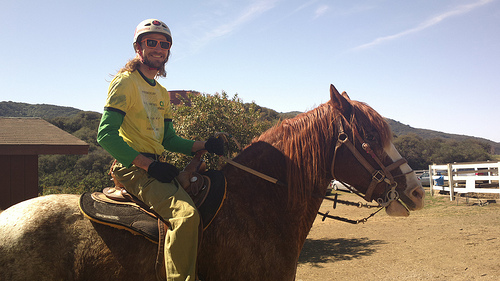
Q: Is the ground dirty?
A: Yes, the ground is dirty.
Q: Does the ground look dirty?
A: Yes, the ground is dirty.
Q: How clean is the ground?
A: The ground is dirty.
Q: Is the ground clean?
A: No, the ground is dirty.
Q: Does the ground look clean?
A: No, the ground is dirty.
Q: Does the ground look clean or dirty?
A: The ground is dirty.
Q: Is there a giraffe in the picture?
A: No, there are no giraffes.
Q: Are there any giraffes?
A: No, there are no giraffes.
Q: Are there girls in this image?
A: No, there are no girls.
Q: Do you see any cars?
A: No, there are no cars.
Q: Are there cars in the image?
A: No, there are no cars.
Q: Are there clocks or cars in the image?
A: No, there are no cars or clocks.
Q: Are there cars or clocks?
A: No, there are no cars or clocks.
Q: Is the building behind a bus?
A: No, the building is behind a man.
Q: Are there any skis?
A: No, there are no skis.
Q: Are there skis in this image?
A: No, there are no skis.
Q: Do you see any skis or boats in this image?
A: No, there are no skis or boats.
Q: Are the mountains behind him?
A: Yes, the mountains are behind the man.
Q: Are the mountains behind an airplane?
A: No, the mountains are behind the man.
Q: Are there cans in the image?
A: No, there are no cans.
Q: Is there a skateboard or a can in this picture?
A: No, there are no cans or skateboards.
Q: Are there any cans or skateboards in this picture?
A: No, there are no cans or skateboards.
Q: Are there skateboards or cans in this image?
A: No, there are no cans or skateboards.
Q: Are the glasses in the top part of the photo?
A: Yes, the glasses are in the top of the image.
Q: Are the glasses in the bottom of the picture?
A: No, the glasses are in the top of the image.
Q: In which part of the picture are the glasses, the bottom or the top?
A: The glasses are in the top of the image.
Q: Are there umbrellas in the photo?
A: No, there are no umbrellas.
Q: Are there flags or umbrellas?
A: No, there are no umbrellas or flags.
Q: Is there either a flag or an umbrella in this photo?
A: No, there are no umbrellas or flags.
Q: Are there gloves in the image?
A: Yes, there are gloves.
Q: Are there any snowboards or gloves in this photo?
A: Yes, there are gloves.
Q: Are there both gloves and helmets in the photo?
A: Yes, there are both gloves and a helmet.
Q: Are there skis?
A: No, there are no skis.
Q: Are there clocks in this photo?
A: No, there are no clocks.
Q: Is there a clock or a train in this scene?
A: No, there are no clocks or trains.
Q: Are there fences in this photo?
A: Yes, there is a fence.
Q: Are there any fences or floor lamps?
A: Yes, there is a fence.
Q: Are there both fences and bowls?
A: No, there is a fence but no bowls.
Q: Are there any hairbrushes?
A: No, there are no hairbrushes.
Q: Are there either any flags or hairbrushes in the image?
A: No, there are no hairbrushes or flags.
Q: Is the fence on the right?
A: Yes, the fence is on the right of the image.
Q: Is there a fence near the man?
A: Yes, there is a fence near the man.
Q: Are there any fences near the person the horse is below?
A: Yes, there is a fence near the man.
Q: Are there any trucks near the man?
A: No, there is a fence near the man.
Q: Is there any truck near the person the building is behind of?
A: No, there is a fence near the man.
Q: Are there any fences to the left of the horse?
A: No, the fence is to the right of the horse.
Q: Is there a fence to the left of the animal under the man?
A: No, the fence is to the right of the horse.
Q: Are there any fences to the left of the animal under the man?
A: No, the fence is to the right of the horse.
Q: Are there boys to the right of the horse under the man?
A: No, there is a fence to the right of the horse.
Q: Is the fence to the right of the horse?
A: Yes, the fence is to the right of the horse.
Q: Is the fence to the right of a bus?
A: No, the fence is to the right of the horse.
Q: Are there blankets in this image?
A: Yes, there is a blanket.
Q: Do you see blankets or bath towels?
A: Yes, there is a blanket.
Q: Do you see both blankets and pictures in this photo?
A: No, there is a blanket but no pictures.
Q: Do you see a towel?
A: No, there are no towels.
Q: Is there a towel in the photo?
A: No, there are no towels.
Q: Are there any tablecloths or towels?
A: No, there are no towels or tablecloths.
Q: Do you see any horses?
A: Yes, there is a horse.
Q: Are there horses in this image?
A: Yes, there is a horse.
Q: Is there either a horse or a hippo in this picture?
A: Yes, there is a horse.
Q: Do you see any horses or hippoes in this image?
A: Yes, there is a horse.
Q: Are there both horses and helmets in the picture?
A: Yes, there are both a horse and a helmet.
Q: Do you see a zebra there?
A: No, there are no zebras.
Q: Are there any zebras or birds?
A: No, there are no zebras or birds.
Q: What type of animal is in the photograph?
A: The animal is a horse.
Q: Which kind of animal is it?
A: The animal is a horse.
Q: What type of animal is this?
A: This is a horse.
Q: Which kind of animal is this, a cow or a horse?
A: This is a horse.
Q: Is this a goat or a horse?
A: This is a horse.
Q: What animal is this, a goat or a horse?
A: This is a horse.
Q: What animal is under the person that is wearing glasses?
A: The horse is under the man.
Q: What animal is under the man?
A: The horse is under the man.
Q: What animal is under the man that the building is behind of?
A: The animal is a horse.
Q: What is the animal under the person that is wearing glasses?
A: The animal is a horse.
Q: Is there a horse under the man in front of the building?
A: Yes, there is a horse under the man.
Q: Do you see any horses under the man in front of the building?
A: Yes, there is a horse under the man.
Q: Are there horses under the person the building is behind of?
A: Yes, there is a horse under the man.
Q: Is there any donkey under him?
A: No, there is a horse under the man.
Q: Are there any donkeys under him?
A: No, there is a horse under the man.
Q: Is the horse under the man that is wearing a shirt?
A: Yes, the horse is under the man.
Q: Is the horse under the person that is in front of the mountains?
A: Yes, the horse is under the man.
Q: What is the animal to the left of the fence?
A: The animal is a horse.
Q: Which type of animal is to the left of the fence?
A: The animal is a horse.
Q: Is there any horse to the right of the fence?
A: No, the horse is to the left of the fence.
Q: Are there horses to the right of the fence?
A: No, the horse is to the left of the fence.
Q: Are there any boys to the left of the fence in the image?
A: No, there is a horse to the left of the fence.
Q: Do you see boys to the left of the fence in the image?
A: No, there is a horse to the left of the fence.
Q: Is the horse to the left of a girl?
A: No, the horse is to the left of a fence.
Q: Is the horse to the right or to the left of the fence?
A: The horse is to the left of the fence.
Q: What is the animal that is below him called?
A: The animal is a horse.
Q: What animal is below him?
A: The animal is a horse.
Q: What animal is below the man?
A: The animal is a horse.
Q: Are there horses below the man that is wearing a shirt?
A: Yes, there is a horse below the man.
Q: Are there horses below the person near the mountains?
A: Yes, there is a horse below the man.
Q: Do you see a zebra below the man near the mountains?
A: No, there is a horse below the man.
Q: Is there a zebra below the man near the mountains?
A: No, there is a horse below the man.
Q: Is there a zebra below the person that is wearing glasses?
A: No, there is a horse below the man.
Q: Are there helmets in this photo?
A: Yes, there is a helmet.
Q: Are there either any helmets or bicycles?
A: Yes, there is a helmet.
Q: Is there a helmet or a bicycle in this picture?
A: Yes, there is a helmet.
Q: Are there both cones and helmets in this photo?
A: No, there is a helmet but no cones.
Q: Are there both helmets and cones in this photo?
A: No, there is a helmet but no cones.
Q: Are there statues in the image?
A: No, there are no statues.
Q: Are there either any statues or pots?
A: No, there are no statues or pots.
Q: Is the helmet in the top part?
A: Yes, the helmet is in the top of the image.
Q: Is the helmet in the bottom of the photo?
A: No, the helmet is in the top of the image.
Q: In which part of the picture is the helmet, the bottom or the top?
A: The helmet is in the top of the image.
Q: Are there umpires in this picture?
A: No, there are no umpires.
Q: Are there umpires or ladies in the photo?
A: No, there are no umpires or ladies.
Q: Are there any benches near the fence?
A: No, there is a man near the fence.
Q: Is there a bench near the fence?
A: No, there is a man near the fence.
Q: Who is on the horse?
A: The man is on the horse.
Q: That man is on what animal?
A: The man is on the horse.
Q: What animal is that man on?
A: The man is on the horse.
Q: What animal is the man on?
A: The man is on the horse.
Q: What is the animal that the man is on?
A: The animal is a horse.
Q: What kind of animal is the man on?
A: The man is on the horse.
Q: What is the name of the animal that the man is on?
A: The animal is a horse.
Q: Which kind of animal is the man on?
A: The man is on the horse.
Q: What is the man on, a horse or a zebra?
A: The man is on a horse.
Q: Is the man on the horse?
A: Yes, the man is on the horse.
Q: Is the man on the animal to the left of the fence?
A: Yes, the man is on the horse.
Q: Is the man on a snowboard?
A: No, the man is on the horse.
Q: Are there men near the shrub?
A: Yes, there is a man near the shrub.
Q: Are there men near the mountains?
A: Yes, there is a man near the mountains.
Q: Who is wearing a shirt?
A: The man is wearing a shirt.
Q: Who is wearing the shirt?
A: The man is wearing a shirt.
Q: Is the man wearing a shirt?
A: Yes, the man is wearing a shirt.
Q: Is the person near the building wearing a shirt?
A: Yes, the man is wearing a shirt.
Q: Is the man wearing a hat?
A: No, the man is wearing a shirt.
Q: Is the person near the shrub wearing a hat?
A: No, the man is wearing a shirt.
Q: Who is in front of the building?
A: The man is in front of the building.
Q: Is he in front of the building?
A: Yes, the man is in front of the building.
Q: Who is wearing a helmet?
A: The man is wearing a helmet.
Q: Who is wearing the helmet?
A: The man is wearing a helmet.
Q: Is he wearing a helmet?
A: Yes, the man is wearing a helmet.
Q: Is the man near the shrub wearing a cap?
A: No, the man is wearing a helmet.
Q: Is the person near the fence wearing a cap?
A: No, the man is wearing a helmet.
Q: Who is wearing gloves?
A: The man is wearing gloves.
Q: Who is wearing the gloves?
A: The man is wearing gloves.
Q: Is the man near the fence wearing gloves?
A: Yes, the man is wearing gloves.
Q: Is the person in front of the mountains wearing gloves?
A: Yes, the man is wearing gloves.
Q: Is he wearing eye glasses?
A: No, the man is wearing gloves.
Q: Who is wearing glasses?
A: The man is wearing glasses.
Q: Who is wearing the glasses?
A: The man is wearing glasses.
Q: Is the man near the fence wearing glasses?
A: Yes, the man is wearing glasses.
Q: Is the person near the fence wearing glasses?
A: Yes, the man is wearing glasses.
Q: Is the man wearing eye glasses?
A: No, the man is wearing glasses.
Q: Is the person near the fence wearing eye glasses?
A: No, the man is wearing glasses.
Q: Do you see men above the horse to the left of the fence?
A: Yes, there is a man above the horse.